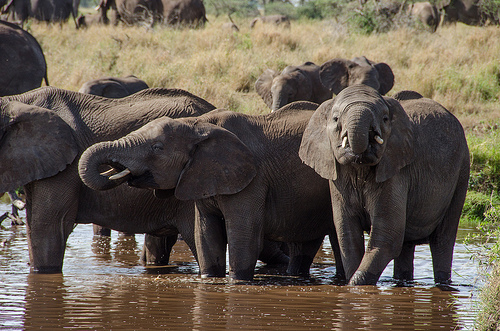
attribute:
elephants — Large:
[1, 49, 486, 294]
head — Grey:
[285, 60, 434, 207]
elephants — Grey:
[0, 18, 473, 296]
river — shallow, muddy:
[18, 282, 480, 324]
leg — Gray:
[203, 195, 235, 276]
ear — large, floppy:
[175, 124, 267, 207]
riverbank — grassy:
[49, 63, 496, 194]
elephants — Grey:
[2, 1, 208, 31]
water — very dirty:
[0, 202, 498, 329]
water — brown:
[2, 210, 494, 323]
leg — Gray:
[350, 190, 406, 285]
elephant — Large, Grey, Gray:
[298, 84, 473, 284]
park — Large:
[11, 8, 483, 330]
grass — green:
[1, 13, 496, 228]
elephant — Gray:
[307, 85, 457, 305]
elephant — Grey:
[313, 66, 498, 278]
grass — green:
[424, 31, 498, 98]